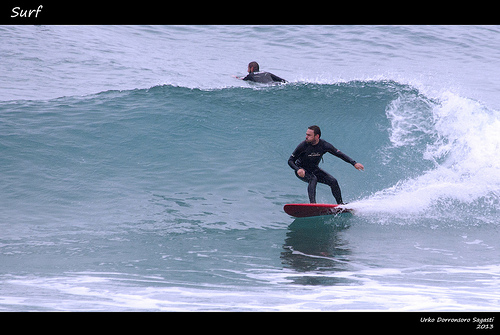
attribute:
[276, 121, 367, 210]
suit — black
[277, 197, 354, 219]
surfboard — red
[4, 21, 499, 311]
water — blue, nice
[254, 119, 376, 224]
person — surfing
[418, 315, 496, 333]
logo — white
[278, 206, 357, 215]
surfboard — red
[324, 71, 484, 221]
foam — white